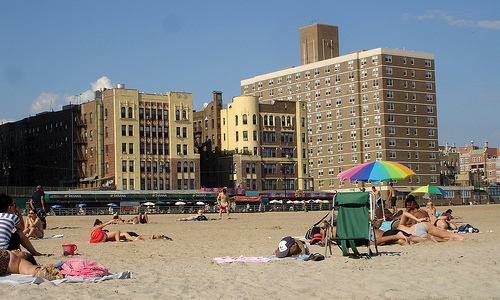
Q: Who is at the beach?
A: Beach-goers.